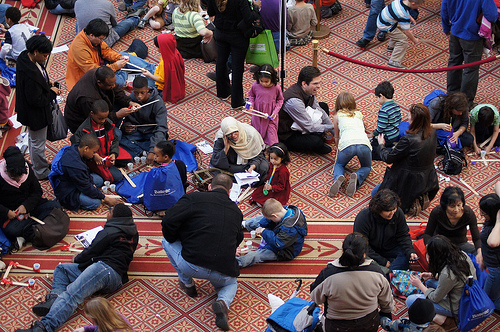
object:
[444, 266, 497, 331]
backpack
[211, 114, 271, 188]
woman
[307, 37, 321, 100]
barrier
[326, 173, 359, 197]
shoes.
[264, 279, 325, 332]
stroller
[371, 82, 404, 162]
boy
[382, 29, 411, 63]
pants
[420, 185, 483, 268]
woman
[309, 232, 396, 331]
woman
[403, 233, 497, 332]
woman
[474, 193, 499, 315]
woman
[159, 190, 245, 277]
shirt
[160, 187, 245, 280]
coat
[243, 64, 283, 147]
girl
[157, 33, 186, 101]
red jacket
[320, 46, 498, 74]
red rope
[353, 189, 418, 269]
person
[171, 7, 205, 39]
striped shirt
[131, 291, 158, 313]
ground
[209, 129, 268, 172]
coat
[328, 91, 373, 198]
girl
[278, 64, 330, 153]
man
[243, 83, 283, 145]
dress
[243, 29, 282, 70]
bag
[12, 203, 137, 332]
man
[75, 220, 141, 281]
jacket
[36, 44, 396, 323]
floor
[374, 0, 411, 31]
shirt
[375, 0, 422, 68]
boy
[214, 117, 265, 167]
wrap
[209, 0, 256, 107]
woman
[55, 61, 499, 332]
groups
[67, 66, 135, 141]
down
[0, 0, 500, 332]
people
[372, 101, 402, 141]
shirt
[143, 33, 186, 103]
boys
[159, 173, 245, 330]
man